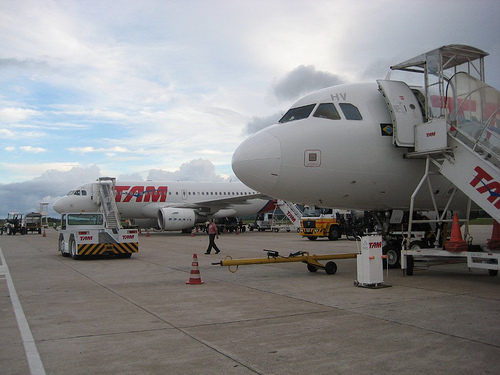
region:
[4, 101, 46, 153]
White clouds in the sky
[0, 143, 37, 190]
White clouds in the sky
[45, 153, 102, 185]
White clouds in the sky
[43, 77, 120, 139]
White clouds in the sky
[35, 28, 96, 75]
White clouds in the sky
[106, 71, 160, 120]
White clouds in the sky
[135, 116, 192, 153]
White clouds in the sky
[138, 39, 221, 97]
White clouds in the sky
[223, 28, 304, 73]
White clouds in the sky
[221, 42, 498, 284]
Airplane in the forefront.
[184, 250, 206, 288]
Orange and white cone on the ground.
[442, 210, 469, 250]
Orange cone on under the stairs.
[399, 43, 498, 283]
Stairs on the side of the plane.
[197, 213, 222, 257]
Person walking on the ground.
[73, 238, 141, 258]
Black and yellow colors on back of vehicle.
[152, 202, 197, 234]
Engine on the plane.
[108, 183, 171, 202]
Red lettering on the plane.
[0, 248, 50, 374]
White lines on the pavement.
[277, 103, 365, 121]
windows on the front of the plane.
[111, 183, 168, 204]
The word TAM on the side of the plane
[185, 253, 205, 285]
a white striped orange cone on the runway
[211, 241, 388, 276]
yellow wheeled piece of equipment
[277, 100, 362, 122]
front windows in an airplane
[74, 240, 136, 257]
yellow and black stripes on back of truck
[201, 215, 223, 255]
person standing on runway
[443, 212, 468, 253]
orange cones on side of plane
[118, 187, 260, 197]
row of windows along airplane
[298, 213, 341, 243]
yellow truck on runway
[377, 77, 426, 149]
open door of airplane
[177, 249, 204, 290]
an orange striped traffic cone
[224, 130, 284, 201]
the nose cone to a plane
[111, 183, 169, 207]
red text on a passenger plane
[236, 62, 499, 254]
a plane parked at an airport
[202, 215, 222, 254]
a man walking between two planes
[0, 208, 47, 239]
a car at the airport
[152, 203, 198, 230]
the engine of a passenger plane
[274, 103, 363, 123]
a front windshield of a plane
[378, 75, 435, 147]
a sliding door to a plane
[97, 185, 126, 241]
stairs leading up to a plane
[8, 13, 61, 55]
White clouds in the sky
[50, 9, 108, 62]
White clouds in the sky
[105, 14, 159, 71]
White clouds in the sky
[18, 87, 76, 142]
White clouds in the sky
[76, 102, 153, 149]
White clouds in the sky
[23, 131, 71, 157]
White clouds in the sky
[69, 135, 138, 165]
White clouds in the sky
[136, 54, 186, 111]
White clouds in the sky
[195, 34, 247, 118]
White clouds in the sky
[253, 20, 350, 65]
White clouds in the sky